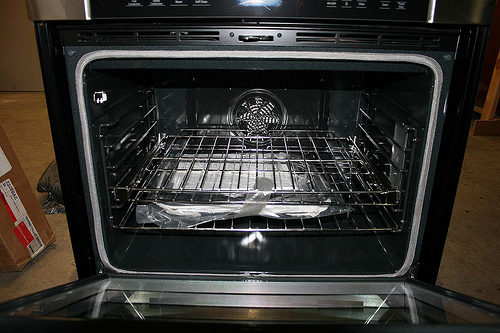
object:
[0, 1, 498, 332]
oven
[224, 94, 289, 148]
fan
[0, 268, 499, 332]
door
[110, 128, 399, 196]
racks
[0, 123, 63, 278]
cardboard box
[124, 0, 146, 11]
buttons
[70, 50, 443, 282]
seal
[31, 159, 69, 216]
bag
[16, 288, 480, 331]
window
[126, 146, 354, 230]
plastic bag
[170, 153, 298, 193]
papers